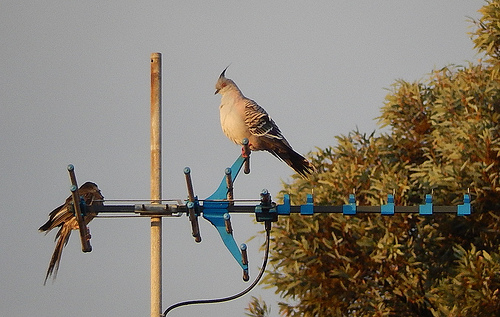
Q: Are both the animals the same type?
A: Yes, all the animals are birds.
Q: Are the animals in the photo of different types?
A: No, all the animals are birds.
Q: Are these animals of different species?
A: No, all the animals are birds.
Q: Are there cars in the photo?
A: No, there are no cars.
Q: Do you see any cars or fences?
A: No, there are no cars or fences.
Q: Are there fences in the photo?
A: No, there are no fences.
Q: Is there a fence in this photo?
A: No, there are no fences.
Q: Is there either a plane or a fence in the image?
A: No, there are no fences or airplanes.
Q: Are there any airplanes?
A: No, there are no airplanes.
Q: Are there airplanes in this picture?
A: No, there are no airplanes.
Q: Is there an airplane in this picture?
A: No, there are no airplanes.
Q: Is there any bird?
A: Yes, there is a bird.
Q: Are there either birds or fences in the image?
A: Yes, there is a bird.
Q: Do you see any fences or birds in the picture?
A: Yes, there is a bird.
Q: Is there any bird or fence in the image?
A: Yes, there is a bird.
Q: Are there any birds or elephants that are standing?
A: Yes, the bird is standing.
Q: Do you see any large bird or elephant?
A: Yes, there is a large bird.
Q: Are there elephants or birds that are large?
A: Yes, the bird is large.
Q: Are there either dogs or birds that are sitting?
A: Yes, the bird is sitting.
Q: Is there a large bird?
A: Yes, there is a large bird.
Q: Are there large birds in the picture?
A: Yes, there is a large bird.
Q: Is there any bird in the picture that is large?
A: Yes, there is a bird that is large.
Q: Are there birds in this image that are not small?
A: Yes, there is a large bird.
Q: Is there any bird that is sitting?
A: Yes, there is a bird that is sitting.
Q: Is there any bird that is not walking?
A: Yes, there is a bird that is sitting.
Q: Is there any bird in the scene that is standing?
A: Yes, there is a bird that is standing.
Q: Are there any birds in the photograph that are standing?
A: Yes, there is a bird that is standing.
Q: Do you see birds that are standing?
A: Yes, there is a bird that is standing.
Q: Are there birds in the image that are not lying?
A: Yes, there is a bird that is standing.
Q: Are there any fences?
A: No, there are no fences.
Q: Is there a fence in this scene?
A: No, there are no fences.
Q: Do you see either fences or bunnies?
A: No, there are no fences or bunnies.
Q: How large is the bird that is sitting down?
A: The bird is large.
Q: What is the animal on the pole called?
A: The animal is a bird.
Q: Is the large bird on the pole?
A: Yes, the bird is on the pole.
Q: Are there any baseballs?
A: No, there are no baseballs.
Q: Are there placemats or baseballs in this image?
A: No, there are no baseballs or placemats.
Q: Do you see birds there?
A: Yes, there is a bird.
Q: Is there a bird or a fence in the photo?
A: Yes, there is a bird.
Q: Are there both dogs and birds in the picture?
A: No, there is a bird but no dogs.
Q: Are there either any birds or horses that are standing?
A: Yes, the bird is standing.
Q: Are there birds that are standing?
A: Yes, there is a bird that is standing.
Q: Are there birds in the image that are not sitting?
A: Yes, there is a bird that is standing.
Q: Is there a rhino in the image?
A: No, there are no rhinos.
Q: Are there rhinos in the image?
A: No, there are no rhinos.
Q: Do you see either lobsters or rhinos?
A: No, there are no rhinos or lobsters.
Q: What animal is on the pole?
A: The bird is on the pole.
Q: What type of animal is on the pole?
A: The animal is a bird.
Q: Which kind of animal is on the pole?
A: The animal is a bird.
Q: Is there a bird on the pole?
A: Yes, there is a bird on the pole.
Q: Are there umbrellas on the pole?
A: No, there is a bird on the pole.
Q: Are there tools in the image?
A: No, there are no tools.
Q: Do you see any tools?
A: No, there are no tools.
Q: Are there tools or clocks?
A: No, there are no tools or clocks.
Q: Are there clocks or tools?
A: No, there are no tools or clocks.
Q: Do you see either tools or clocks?
A: No, there are no tools or clocks.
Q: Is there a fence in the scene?
A: No, there are no fences.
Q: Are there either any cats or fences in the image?
A: No, there are no fences or cats.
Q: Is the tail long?
A: Yes, the tail is long.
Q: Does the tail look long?
A: Yes, the tail is long.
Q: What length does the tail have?
A: The tail has long length.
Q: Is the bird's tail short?
A: No, the tail is long.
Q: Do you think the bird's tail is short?
A: No, the tail is long.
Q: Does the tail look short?
A: No, the tail is long.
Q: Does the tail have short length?
A: No, the tail is long.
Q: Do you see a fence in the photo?
A: No, there are no fences.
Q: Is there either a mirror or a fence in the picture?
A: No, there are no fences or mirrors.